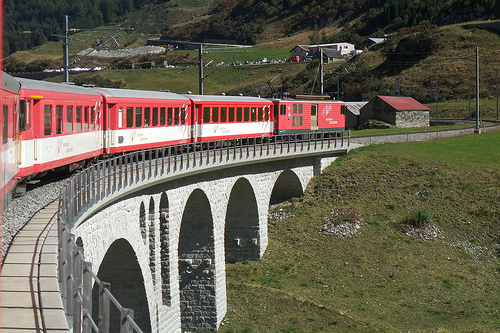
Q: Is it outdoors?
A: Yes, it is outdoors.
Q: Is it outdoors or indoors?
A: It is outdoors.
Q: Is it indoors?
A: No, it is outdoors.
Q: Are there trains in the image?
A: Yes, there is a train.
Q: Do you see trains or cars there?
A: Yes, there is a train.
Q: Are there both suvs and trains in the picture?
A: No, there is a train but no suvs.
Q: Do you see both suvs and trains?
A: No, there is a train but no suvs.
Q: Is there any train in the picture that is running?
A: Yes, there is a train that is running.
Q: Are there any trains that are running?
A: Yes, there is a train that is running.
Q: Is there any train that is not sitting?
A: Yes, there is a train that is running.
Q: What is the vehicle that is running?
A: The vehicle is a train.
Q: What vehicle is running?
A: The vehicle is a train.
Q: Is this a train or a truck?
A: This is a train.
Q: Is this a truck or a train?
A: This is a train.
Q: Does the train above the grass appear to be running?
A: Yes, the train is running.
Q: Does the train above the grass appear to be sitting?
A: No, the train is running.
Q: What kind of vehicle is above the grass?
A: The vehicle is a train.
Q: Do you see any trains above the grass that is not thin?
A: Yes, there is a train above the grass.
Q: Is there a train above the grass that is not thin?
A: Yes, there is a train above the grass.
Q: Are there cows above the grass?
A: No, there is a train above the grass.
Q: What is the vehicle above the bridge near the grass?
A: The vehicle is a train.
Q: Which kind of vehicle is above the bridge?
A: The vehicle is a train.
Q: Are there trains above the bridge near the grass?
A: Yes, there is a train above the bridge.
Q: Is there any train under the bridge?
A: No, the train is above the bridge.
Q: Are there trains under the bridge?
A: No, the train is above the bridge.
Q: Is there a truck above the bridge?
A: No, there is a train above the bridge.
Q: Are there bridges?
A: Yes, there is a bridge.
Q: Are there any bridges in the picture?
A: Yes, there is a bridge.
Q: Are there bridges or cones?
A: Yes, there is a bridge.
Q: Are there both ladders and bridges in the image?
A: No, there is a bridge but no ladders.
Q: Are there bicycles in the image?
A: No, there are no bicycles.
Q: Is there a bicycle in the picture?
A: No, there are no bicycles.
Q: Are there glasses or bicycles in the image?
A: No, there are no bicycles or glasses.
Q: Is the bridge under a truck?
A: No, the bridge is under a train.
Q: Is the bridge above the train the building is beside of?
A: No, the bridge is under the train.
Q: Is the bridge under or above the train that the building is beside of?
A: The bridge is under the train.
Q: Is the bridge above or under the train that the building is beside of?
A: The bridge is under the train.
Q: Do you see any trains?
A: Yes, there is a train.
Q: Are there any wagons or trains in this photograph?
A: Yes, there is a train.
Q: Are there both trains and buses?
A: No, there is a train but no buses.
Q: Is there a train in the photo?
A: Yes, there is a train.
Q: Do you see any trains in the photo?
A: Yes, there is a train.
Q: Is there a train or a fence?
A: Yes, there is a train.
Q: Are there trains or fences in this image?
A: Yes, there is a train.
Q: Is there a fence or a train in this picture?
A: Yes, there is a train.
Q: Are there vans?
A: No, there are no vans.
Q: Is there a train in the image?
A: Yes, there is a train.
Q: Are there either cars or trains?
A: Yes, there is a train.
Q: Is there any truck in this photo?
A: No, there are no trucks.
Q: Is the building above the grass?
A: Yes, the building is above the grass.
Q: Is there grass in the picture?
A: Yes, there is grass.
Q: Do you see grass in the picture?
A: Yes, there is grass.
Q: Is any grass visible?
A: Yes, there is grass.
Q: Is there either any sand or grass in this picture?
A: Yes, there is grass.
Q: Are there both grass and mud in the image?
A: No, there is grass but no mud.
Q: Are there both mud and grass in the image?
A: No, there is grass but no mud.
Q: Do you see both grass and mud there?
A: No, there is grass but no mud.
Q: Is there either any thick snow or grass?
A: Yes, there is thick grass.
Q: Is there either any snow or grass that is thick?
A: Yes, the grass is thick.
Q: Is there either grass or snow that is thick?
A: Yes, the grass is thick.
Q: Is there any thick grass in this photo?
A: Yes, there is thick grass.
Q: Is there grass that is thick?
A: Yes, there is grass that is thick.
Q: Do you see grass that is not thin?
A: Yes, there is thick grass.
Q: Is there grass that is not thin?
A: Yes, there is thick grass.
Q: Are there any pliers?
A: No, there are no pliers.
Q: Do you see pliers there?
A: No, there are no pliers.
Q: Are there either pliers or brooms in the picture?
A: No, there are no pliers or brooms.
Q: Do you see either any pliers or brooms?
A: No, there are no pliers or brooms.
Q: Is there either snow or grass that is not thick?
A: No, there is grass but it is thick.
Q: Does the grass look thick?
A: Yes, the grass is thick.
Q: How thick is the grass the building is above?
A: The grass is thick.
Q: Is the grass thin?
A: No, the grass is thick.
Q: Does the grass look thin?
A: No, the grass is thick.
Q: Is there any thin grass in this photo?
A: No, there is grass but it is thick.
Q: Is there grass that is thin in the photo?
A: No, there is grass but it is thick.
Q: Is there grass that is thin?
A: No, there is grass but it is thick.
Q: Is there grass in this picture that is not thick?
A: No, there is grass but it is thick.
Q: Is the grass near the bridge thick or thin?
A: The grass is thick.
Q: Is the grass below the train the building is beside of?
A: Yes, the grass is below the train.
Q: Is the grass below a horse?
A: No, the grass is below the train.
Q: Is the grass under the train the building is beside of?
A: Yes, the grass is under the train.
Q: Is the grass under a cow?
A: No, the grass is under the train.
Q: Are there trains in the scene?
A: Yes, there is a train.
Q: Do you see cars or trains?
A: Yes, there is a train.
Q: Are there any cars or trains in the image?
A: Yes, there is a train.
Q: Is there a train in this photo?
A: Yes, there is a train.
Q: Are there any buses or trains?
A: Yes, there is a train.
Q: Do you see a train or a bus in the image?
A: Yes, there is a train.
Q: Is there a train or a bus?
A: Yes, there is a train.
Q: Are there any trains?
A: Yes, there is a train.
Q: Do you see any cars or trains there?
A: Yes, there is a train.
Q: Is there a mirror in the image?
A: No, there are no mirrors.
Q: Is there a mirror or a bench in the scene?
A: No, there are no mirrors or benches.